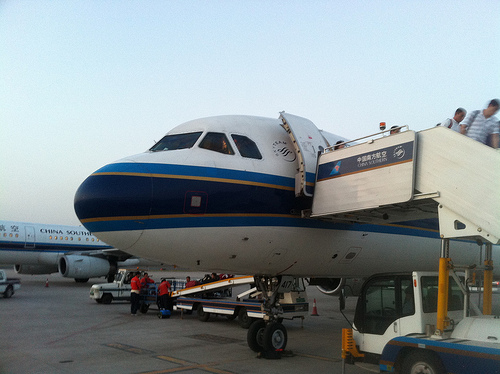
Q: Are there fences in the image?
A: No, there are no fences.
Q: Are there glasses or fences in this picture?
A: No, there are no fences or glasses.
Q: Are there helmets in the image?
A: No, there are no helmets.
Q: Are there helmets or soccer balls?
A: No, there are no helmets or soccer balls.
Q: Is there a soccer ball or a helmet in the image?
A: No, there are no helmets or soccer balls.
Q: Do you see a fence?
A: No, there are no fences.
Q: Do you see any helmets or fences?
A: No, there are no fences or helmets.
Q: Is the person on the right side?
A: Yes, the person is on the right of the image.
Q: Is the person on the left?
A: No, the person is on the right of the image.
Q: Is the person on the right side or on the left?
A: The person is on the right of the image.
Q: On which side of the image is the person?
A: The person is on the right of the image.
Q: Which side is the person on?
A: The person is on the right of the image.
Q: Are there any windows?
A: Yes, there is a window.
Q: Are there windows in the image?
A: Yes, there is a window.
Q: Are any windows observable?
A: Yes, there is a window.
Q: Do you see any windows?
A: Yes, there is a window.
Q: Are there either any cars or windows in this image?
A: Yes, there is a window.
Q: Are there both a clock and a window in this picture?
A: No, there is a window but no clocks.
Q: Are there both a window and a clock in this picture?
A: No, there is a window but no clocks.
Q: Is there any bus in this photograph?
A: No, there are no buses.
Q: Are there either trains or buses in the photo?
A: No, there are no buses or trains.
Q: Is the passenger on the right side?
A: Yes, the passenger is on the right of the image.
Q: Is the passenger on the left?
A: No, the passenger is on the right of the image.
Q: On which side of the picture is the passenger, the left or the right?
A: The passenger is on the right of the image.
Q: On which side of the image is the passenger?
A: The passenger is on the right of the image.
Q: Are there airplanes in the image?
A: Yes, there is an airplane.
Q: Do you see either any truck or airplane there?
A: Yes, there is an airplane.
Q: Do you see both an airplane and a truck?
A: Yes, there are both an airplane and a truck.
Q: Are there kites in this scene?
A: No, there are no kites.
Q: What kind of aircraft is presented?
A: The aircraft is an airplane.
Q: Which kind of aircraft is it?
A: The aircraft is an airplane.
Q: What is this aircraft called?
A: This is an airplane.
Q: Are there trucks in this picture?
A: Yes, there is a truck.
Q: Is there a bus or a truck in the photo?
A: Yes, there is a truck.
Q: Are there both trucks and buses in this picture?
A: No, there is a truck but no buses.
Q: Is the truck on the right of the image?
A: Yes, the truck is on the right of the image.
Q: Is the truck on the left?
A: No, the truck is on the right of the image.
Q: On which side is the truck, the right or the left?
A: The truck is on the right of the image.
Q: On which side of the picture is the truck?
A: The truck is on the right of the image.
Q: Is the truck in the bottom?
A: Yes, the truck is in the bottom of the image.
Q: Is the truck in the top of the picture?
A: No, the truck is in the bottom of the image.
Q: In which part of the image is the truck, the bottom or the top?
A: The truck is in the bottom of the image.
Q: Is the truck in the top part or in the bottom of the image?
A: The truck is in the bottom of the image.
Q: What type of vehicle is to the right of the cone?
A: The vehicle is a truck.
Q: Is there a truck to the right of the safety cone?
A: Yes, there is a truck to the right of the safety cone.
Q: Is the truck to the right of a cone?
A: Yes, the truck is to the right of a cone.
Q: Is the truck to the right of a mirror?
A: No, the truck is to the right of a cone.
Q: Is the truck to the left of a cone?
A: No, the truck is to the right of a cone.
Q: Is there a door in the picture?
A: Yes, there is a door.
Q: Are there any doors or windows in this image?
A: Yes, there is a door.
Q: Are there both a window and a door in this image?
A: Yes, there are both a door and a window.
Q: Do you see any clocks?
A: No, there are no clocks.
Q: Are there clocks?
A: No, there are no clocks.